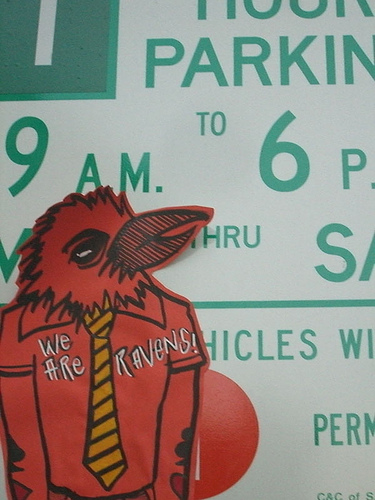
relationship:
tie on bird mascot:
[78, 289, 128, 490] [1, 182, 215, 497]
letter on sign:
[145, 36, 185, 88] [0, 3, 368, 497]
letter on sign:
[313, 412, 328, 446] [0, 3, 368, 497]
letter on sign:
[346, 411, 362, 444] [0, 3, 368, 497]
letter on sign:
[233, 328, 253, 360] [0, 3, 368, 497]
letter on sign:
[256, 327, 274, 360] [0, 3, 368, 497]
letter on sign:
[299, 327, 318, 359] [0, 3, 368, 497]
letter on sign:
[338, 326, 363, 359] [0, 3, 368, 497]